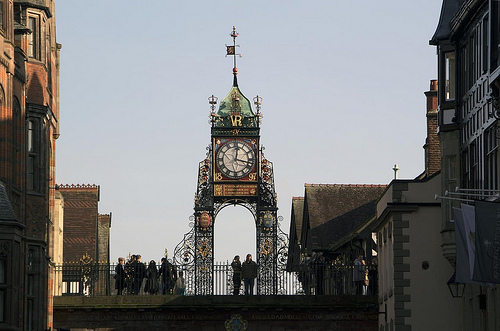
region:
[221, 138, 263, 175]
Black hands on clock.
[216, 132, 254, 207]
Black numbers on clock.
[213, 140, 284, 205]
Numbers on clock are roman numeral.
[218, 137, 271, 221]
Face on clock is round.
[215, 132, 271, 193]
Face on clock is white in color.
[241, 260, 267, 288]
Person wearing dark jacket.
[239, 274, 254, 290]
Person wearing blue jeans.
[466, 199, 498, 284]
Black flag hanging from building.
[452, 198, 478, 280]
White flag hanging from building.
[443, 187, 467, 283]
Gray flag hanging from building.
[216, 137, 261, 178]
clock on top of tower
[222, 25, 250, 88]
weather vane on top of tower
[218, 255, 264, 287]
two people standing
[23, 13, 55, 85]
window in brown building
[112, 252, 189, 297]
group of people standing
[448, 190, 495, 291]
three flags hanging from building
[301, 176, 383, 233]
brown dirty roof of building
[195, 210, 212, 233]
red decoration on tower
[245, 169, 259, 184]
number 97 on the tower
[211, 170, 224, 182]
number 18 on the tower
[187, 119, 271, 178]
A clock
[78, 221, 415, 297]
People at the bottom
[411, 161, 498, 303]
Flags on a building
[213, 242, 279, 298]
A couple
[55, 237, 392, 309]
A gate attached to the clock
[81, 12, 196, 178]
It is daytime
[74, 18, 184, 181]
It is sunny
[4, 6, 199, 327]
This is not America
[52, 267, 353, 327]
They are standing on a building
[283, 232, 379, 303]
Crowd to the right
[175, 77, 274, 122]
top of structure is green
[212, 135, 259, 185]
clock in middle of structure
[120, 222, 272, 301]
people standing near structure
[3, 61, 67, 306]
a shadow of buildings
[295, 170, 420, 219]
the roof is brown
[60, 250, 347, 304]
the fence is made of metal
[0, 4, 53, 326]
the building is red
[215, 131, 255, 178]
clock hands are green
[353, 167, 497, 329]
the building is brown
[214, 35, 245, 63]
flag on top of structure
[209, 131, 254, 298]
two people beneath clock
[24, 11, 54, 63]
one window on side of house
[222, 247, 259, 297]
two people talking to eachother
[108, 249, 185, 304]
a group of people talking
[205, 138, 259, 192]
a clock on top of tower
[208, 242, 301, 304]
two people in black clothes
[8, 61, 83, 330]
shadow on side of building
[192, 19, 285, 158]
tower top over clock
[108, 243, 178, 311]
people standing near clock tower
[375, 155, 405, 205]
cross on building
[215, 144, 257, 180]
black and white clock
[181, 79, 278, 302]
decorative green clock tower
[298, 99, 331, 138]
white clouds in blue sky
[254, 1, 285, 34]
white clouds in blue sky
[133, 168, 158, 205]
white clouds in blue sky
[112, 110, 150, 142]
white clouds in blue sky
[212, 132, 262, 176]
black and white clock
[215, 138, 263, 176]
clock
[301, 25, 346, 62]
white clouds in blue sky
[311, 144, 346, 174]
white clouds in blue sky